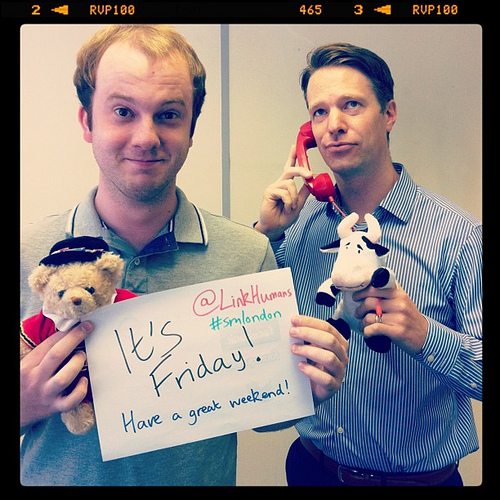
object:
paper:
[76, 264, 319, 466]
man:
[16, 24, 350, 489]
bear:
[20, 232, 138, 438]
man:
[252, 35, 484, 489]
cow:
[313, 206, 400, 358]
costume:
[19, 232, 141, 440]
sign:
[75, 262, 317, 464]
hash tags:
[207, 308, 283, 332]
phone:
[291, 116, 340, 208]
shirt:
[254, 162, 483, 474]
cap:
[35, 233, 115, 269]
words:
[144, 345, 253, 405]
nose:
[70, 296, 84, 307]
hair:
[296, 39, 396, 147]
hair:
[66, 24, 211, 137]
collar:
[317, 158, 419, 229]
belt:
[298, 434, 460, 486]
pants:
[281, 433, 465, 488]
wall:
[20, 24, 482, 488]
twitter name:
[193, 282, 295, 318]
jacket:
[21, 289, 139, 402]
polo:
[20, 185, 280, 487]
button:
[426, 354, 435, 364]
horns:
[362, 211, 383, 245]